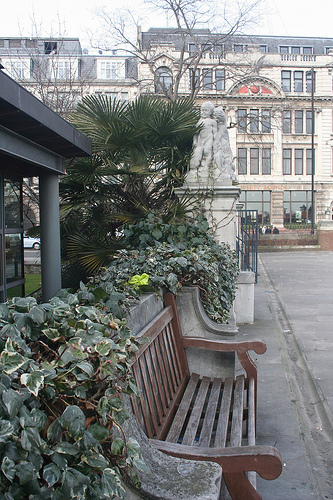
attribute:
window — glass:
[17, 23, 330, 251]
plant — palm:
[80, 100, 192, 249]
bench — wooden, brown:
[47, 292, 283, 487]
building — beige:
[2, 34, 331, 275]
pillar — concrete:
[28, 173, 69, 297]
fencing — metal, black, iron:
[233, 207, 261, 275]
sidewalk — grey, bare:
[257, 239, 331, 496]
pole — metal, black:
[303, 64, 322, 247]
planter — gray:
[10, 237, 236, 335]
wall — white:
[230, 277, 258, 328]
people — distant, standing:
[259, 218, 280, 243]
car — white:
[17, 231, 42, 254]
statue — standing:
[186, 101, 227, 190]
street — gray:
[272, 249, 322, 387]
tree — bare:
[152, 187, 242, 240]